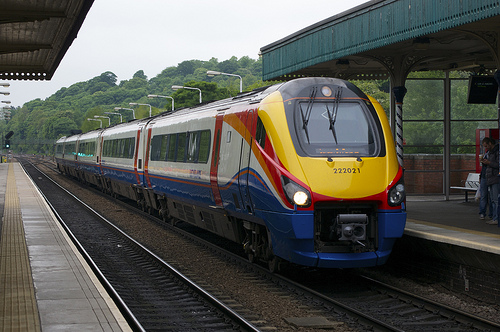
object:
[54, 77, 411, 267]
train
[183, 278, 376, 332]
tracks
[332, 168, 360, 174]
numbers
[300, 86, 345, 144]
wipers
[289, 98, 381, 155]
windshield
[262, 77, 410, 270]
front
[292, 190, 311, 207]
headlight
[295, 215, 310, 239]
paint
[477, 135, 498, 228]
people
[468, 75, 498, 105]
sign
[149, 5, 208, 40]
sky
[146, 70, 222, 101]
lights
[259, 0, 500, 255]
station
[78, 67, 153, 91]
trees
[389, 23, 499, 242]
train stop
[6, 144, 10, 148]
light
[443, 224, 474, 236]
line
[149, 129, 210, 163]
windows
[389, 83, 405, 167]
pole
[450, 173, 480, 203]
bench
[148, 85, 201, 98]
row